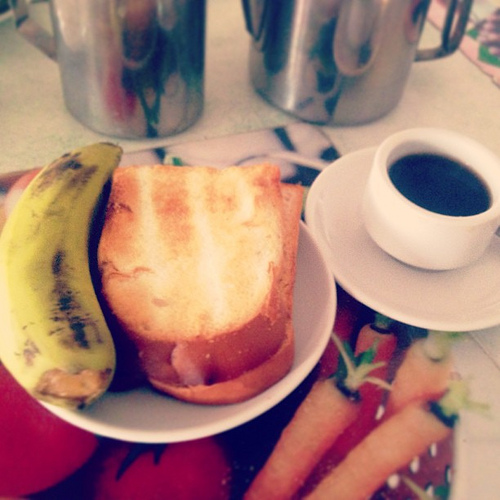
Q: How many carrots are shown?
A: 4.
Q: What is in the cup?
A: Coffee.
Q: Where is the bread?
A: Next to the banana.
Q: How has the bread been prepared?
A: Toasted.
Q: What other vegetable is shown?
A: Tomatoes.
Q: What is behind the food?
A: 2 metal canisters.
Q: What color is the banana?
A: Yellow.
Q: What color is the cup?
A: White.